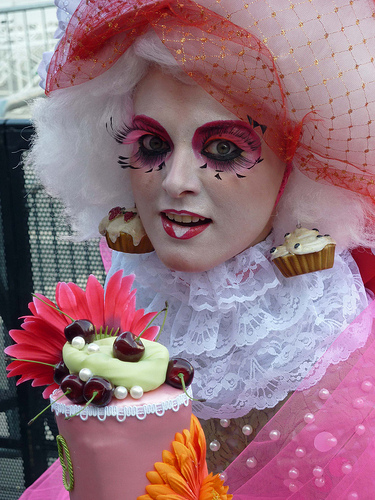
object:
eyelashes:
[105, 116, 267, 181]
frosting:
[271, 228, 336, 260]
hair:
[12, 0, 375, 256]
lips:
[160, 209, 214, 240]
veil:
[18, 289, 375, 500]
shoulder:
[243, 266, 375, 500]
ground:
[281, 71, 307, 94]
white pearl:
[242, 424, 252, 435]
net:
[45, 0, 373, 201]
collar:
[102, 229, 373, 420]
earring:
[98, 204, 155, 255]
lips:
[161, 216, 212, 239]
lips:
[159, 209, 211, 219]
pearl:
[130, 386, 143, 399]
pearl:
[114, 386, 128, 400]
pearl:
[72, 336, 85, 350]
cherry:
[167, 358, 205, 402]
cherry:
[64, 375, 115, 420]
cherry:
[30, 373, 84, 424]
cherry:
[3, 358, 70, 385]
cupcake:
[269, 224, 336, 278]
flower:
[139, 415, 235, 500]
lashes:
[199, 115, 267, 182]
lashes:
[105, 116, 170, 174]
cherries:
[12, 292, 205, 424]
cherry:
[113, 307, 166, 362]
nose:
[161, 146, 201, 197]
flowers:
[4, 271, 232, 500]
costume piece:
[3, 268, 229, 500]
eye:
[139, 133, 170, 152]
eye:
[201, 138, 245, 161]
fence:
[0, 122, 92, 500]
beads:
[341, 465, 351, 475]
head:
[106, 49, 284, 272]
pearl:
[79, 368, 90, 381]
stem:
[135, 306, 167, 342]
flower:
[2, 268, 159, 398]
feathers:
[118, 148, 166, 173]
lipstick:
[172, 225, 190, 237]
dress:
[18, 228, 375, 500]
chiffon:
[19, 286, 374, 500]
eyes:
[136, 133, 243, 161]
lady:
[17, 0, 374, 499]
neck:
[104, 230, 329, 420]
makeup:
[105, 115, 266, 240]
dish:
[48, 383, 191, 500]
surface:
[50, 384, 193, 422]